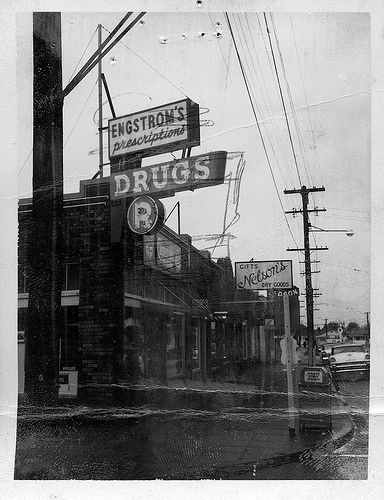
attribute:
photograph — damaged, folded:
[1, 0, 383, 499]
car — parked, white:
[330, 343, 369, 379]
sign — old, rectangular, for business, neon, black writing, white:
[108, 101, 202, 150]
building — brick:
[22, 176, 204, 411]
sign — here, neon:
[237, 262, 295, 289]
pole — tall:
[284, 186, 326, 362]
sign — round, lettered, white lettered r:
[122, 195, 163, 237]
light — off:
[344, 231, 358, 241]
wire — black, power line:
[221, 15, 302, 247]